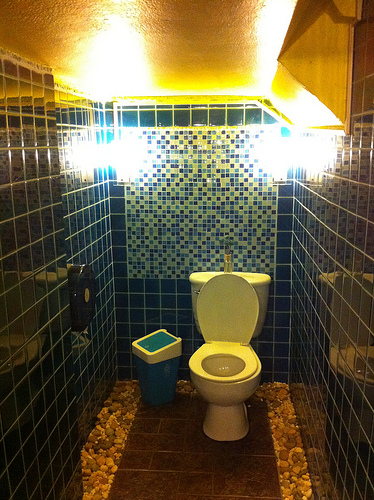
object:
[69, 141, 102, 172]
lights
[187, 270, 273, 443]
toilet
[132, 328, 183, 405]
trash can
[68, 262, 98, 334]
dispenser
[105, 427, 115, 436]
rocks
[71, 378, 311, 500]
ground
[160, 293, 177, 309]
tile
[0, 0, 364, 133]
ceiling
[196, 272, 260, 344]
lid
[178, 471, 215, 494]
tile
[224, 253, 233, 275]
bottle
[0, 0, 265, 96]
popcorn surace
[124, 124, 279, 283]
tiles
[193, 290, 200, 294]
handle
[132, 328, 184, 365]
white lid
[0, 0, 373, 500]
bathroom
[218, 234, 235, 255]
plant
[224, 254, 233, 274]
vase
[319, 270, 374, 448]
reflection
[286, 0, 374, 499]
wall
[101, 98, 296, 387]
wall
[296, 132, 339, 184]
reflection